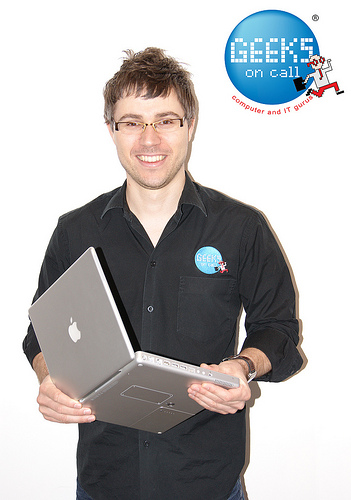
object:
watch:
[221, 353, 257, 384]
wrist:
[219, 349, 265, 391]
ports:
[150, 353, 199, 376]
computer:
[27, 245, 240, 436]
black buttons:
[146, 304, 155, 314]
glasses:
[108, 112, 188, 136]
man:
[24, 44, 307, 500]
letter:
[238, 35, 285, 69]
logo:
[66, 315, 83, 345]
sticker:
[188, 238, 236, 284]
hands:
[35, 370, 96, 425]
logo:
[192, 245, 231, 277]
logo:
[218, 7, 346, 118]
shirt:
[20, 169, 305, 500]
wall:
[2, 6, 95, 139]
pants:
[228, 479, 249, 497]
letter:
[195, 253, 205, 261]